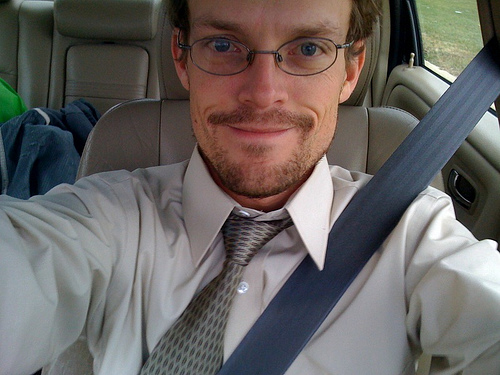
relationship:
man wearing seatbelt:
[0, 0, 500, 374] [217, 36, 499, 374]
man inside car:
[0, 0, 500, 374] [0, 1, 498, 372]